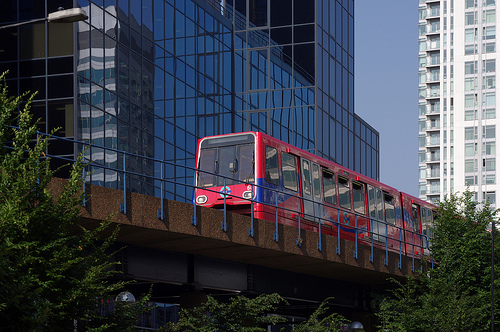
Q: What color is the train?
A: Red.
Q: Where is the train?
A: On a track in a city.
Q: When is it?
A: Daytime.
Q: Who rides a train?
A: People.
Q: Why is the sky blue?
A: It is daytime.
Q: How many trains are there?
A: One.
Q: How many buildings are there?
A: Two.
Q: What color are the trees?
A: Green.